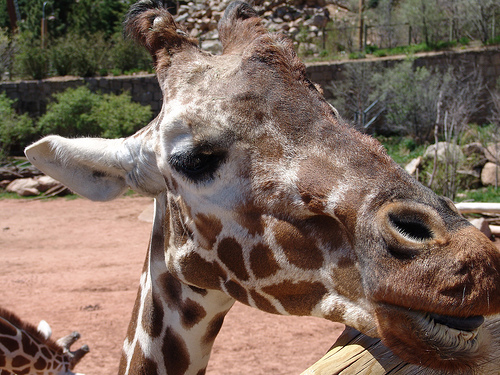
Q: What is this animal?
A: Giraffe.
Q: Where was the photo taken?
A: At a zoo.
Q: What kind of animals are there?
A: Giraffes.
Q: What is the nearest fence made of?
A: Wood.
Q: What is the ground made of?
A: Dirt.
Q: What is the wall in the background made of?
A: Stone.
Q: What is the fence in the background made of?
A: Metal.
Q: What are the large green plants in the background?
A: Trees.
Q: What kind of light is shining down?
A: Sunlight.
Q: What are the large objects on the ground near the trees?
A: Rocks.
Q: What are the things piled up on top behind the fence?
A: Rocks.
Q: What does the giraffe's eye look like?
A: Dark.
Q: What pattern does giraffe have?
A: Spotted.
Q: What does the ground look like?
A: Dusty.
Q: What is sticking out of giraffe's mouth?
A: Tongue.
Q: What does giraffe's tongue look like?
A: Black.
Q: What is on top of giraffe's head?
A: Horns.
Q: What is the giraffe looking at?
A: Camera.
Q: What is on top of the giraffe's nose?
A: Nostrils.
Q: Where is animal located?
A: A zoo.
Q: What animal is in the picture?
A: A giraffe.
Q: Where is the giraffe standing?
A: On the dirt.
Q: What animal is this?
A: Giraffe.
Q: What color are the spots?
A: Brown.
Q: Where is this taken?
A: Zoo.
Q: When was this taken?
A: Day time.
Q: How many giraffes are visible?
A: Two.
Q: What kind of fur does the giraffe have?
A: Short.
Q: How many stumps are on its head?
A: Two.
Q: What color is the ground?
A: Brown.